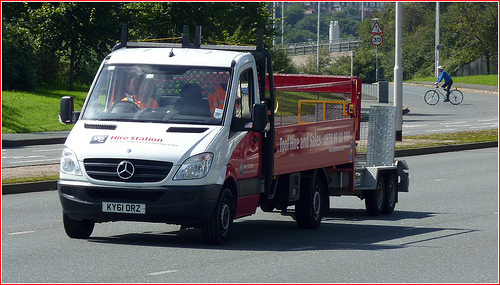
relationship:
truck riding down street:
[59, 42, 415, 236] [7, 82, 500, 284]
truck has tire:
[59, 42, 415, 236] [204, 185, 238, 246]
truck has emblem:
[59, 42, 415, 236] [115, 159, 138, 179]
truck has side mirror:
[59, 42, 415, 236] [246, 98, 272, 135]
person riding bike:
[436, 66, 453, 100] [422, 83, 466, 104]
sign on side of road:
[369, 20, 392, 91] [7, 82, 500, 284]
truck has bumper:
[59, 42, 415, 236] [54, 182, 224, 225]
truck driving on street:
[59, 42, 415, 236] [7, 82, 500, 284]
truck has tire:
[59, 42, 415, 236] [63, 208, 97, 242]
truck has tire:
[59, 42, 415, 236] [297, 178, 326, 224]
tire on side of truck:
[204, 185, 238, 246] [59, 42, 415, 236]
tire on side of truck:
[63, 208, 97, 242] [59, 42, 415, 236]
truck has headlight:
[59, 42, 415, 236] [173, 151, 214, 180]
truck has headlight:
[59, 42, 415, 236] [57, 147, 84, 176]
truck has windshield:
[59, 42, 415, 236] [80, 65, 231, 124]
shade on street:
[87, 205, 477, 252] [7, 82, 500, 284]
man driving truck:
[110, 78, 160, 114] [59, 42, 415, 236]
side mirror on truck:
[246, 98, 272, 135] [59, 42, 415, 236]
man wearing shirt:
[110, 78, 160, 114] [127, 98, 162, 111]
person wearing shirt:
[436, 66, 453, 100] [436, 72, 450, 85]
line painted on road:
[149, 267, 176, 278] [7, 82, 500, 284]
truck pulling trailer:
[59, 42, 415, 236] [255, 71, 413, 227]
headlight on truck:
[173, 151, 214, 180] [59, 42, 415, 236]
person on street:
[436, 66, 453, 100] [7, 82, 500, 284]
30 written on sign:
[374, 33, 381, 46] [369, 20, 392, 91]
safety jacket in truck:
[207, 84, 238, 119] [59, 42, 415, 236]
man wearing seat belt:
[110, 78, 160, 114] [121, 91, 138, 104]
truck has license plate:
[59, 42, 415, 236] [93, 202, 150, 217]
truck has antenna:
[59, 42, 415, 236] [164, 28, 180, 60]